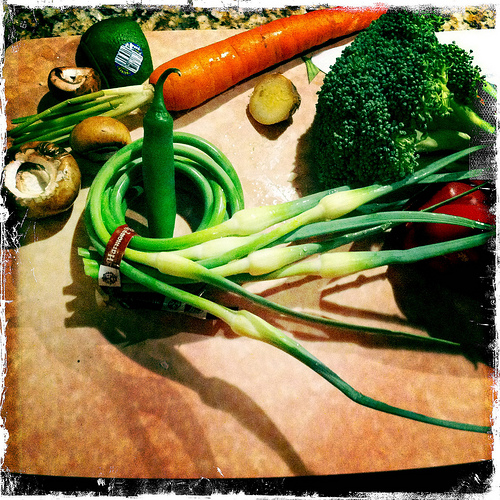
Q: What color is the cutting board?
A: Brown.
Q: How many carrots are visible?
A: One.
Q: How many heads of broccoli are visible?
A: One.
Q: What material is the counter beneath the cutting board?
A: Marble.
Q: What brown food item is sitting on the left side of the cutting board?
A: Mushrooms.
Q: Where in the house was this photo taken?
A: The kitchen.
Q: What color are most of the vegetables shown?
A: Green.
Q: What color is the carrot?
A: Orange.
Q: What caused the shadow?
A: An overhead light.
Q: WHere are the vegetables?
A: On a table.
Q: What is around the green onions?
A: A sticker.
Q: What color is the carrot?
A: Orange.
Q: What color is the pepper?
A: Green.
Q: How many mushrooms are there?
A: Three.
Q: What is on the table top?
A: Vegetables.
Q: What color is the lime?
A: Green.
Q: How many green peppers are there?
A: 1.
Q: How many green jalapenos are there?
A: 1.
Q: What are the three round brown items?
A: Mushrooms.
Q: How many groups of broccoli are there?
A: 1.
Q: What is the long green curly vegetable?
A: Spring onion.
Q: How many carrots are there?
A: 1.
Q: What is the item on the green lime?
A: Sticker.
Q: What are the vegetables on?
A: Brown sheet.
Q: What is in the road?
A: White lines.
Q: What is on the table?
A: An assortment of fresh vegetables.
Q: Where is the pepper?
A: In the onions.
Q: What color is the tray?
A: Brown.